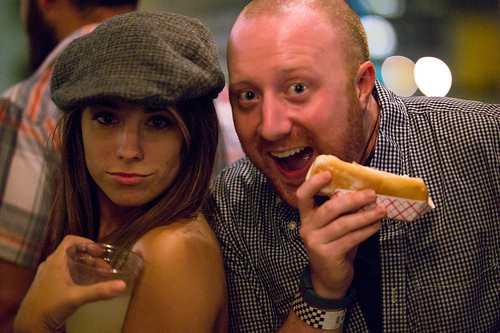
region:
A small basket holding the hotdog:
[327, 189, 432, 219]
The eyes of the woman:
[93, 112, 168, 129]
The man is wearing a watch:
[295, 272, 350, 306]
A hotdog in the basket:
[307, 156, 427, 201]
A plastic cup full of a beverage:
[66, 244, 143, 331]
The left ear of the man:
[355, 62, 377, 107]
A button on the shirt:
[286, 219, 297, 230]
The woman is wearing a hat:
[52, 12, 223, 100]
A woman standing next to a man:
[12, 1, 497, 330]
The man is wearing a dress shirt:
[208, 82, 498, 332]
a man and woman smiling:
[13, 5, 478, 319]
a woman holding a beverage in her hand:
[20, 13, 220, 313]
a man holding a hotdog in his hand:
[214, 1, 446, 230]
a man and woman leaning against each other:
[36, 0, 434, 280]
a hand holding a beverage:
[23, 229, 141, 329]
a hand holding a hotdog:
[292, 143, 438, 277]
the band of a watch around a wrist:
[294, 265, 359, 315]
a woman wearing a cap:
[46, 12, 223, 227]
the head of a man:
[221, 3, 393, 217]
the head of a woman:
[46, 18, 221, 204]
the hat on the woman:
[49, 13, 224, 112]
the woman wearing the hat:
[12, 11, 226, 331]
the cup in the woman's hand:
[65, 242, 141, 332]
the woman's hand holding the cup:
[13, 233, 126, 330]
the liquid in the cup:
[67, 293, 133, 332]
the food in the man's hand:
[305, 153, 436, 221]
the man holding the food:
[202, 0, 498, 332]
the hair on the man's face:
[237, 75, 364, 206]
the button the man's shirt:
[287, 219, 296, 231]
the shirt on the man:
[202, 78, 499, 331]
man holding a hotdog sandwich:
[216, 14, 463, 284]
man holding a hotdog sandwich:
[222, 27, 460, 296]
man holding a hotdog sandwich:
[220, 7, 416, 296]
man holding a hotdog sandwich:
[223, 27, 445, 322]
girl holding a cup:
[20, 31, 214, 324]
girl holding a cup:
[26, 28, 226, 303]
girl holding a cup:
[23, 30, 228, 330]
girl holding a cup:
[20, 30, 224, 309]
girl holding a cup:
[28, 19, 256, 287]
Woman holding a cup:
[55, 231, 143, 331]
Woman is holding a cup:
[60, 233, 145, 330]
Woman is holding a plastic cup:
[57, 240, 142, 330]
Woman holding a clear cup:
[52, 239, 153, 328]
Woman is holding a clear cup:
[62, 240, 146, 330]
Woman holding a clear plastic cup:
[55, 236, 150, 330]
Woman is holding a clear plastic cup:
[57, 240, 142, 328]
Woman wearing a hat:
[45, 10, 230, 110]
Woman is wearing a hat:
[45, 7, 231, 110]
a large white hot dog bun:
[306, 150, 427, 215]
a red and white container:
[313, 180, 434, 222]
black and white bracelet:
[281, 288, 348, 328]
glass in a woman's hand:
[52, 238, 139, 308]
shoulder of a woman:
[131, 214, 219, 304]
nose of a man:
[251, 89, 292, 140]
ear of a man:
[353, 48, 381, 105]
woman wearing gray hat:
[12, 11, 231, 330]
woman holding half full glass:
[0, 9, 231, 330]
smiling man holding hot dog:
[208, 0, 498, 331]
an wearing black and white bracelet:
[284, 290, 344, 330]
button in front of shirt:
[283, 218, 299, 233]